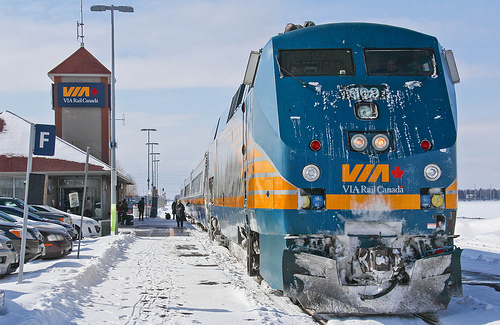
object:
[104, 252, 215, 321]
snow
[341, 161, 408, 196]
writing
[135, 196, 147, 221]
person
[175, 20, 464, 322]
train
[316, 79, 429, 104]
snow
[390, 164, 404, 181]
leaf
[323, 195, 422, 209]
lines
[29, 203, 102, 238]
cars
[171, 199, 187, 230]
person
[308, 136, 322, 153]
light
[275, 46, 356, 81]
windows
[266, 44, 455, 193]
front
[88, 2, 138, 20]
lights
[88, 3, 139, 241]
poles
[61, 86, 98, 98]
logo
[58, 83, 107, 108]
sign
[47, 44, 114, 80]
roof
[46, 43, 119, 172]
tower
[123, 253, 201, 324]
track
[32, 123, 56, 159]
sign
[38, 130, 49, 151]
letter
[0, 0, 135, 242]
station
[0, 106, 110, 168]
snow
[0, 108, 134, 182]
roof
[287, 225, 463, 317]
catcher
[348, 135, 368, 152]
lights